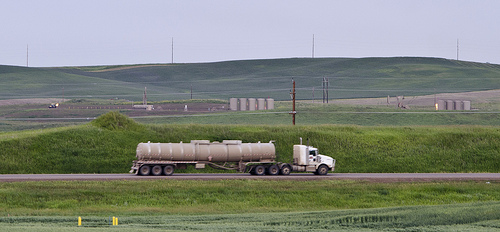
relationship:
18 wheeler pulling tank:
[129, 137, 337, 176] [132, 104, 289, 172]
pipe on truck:
[299, 132, 304, 145] [129, 132, 335, 175]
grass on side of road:
[2, 181, 497, 230] [2, 170, 497, 180]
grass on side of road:
[3, 118, 498, 174] [2, 170, 497, 180]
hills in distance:
[3, 55, 488, 97] [21, 60, 494, 137]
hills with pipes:
[0, 56, 500, 109] [190, 80, 280, 115]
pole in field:
[289, 75, 301, 124] [156, 78, 439, 122]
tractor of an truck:
[289, 133, 347, 193] [127, 126, 378, 182]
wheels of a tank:
[135, 161, 186, 178] [135, 139, 276, 161]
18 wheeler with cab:
[131, 137, 334, 176] [288, 135, 335, 173]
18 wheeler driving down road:
[129, 137, 337, 176] [34, 156, 498, 196]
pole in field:
[289, 78, 296, 126] [21, 113, 491, 172]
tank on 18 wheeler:
[132, 136, 278, 168] [129, 137, 337, 176]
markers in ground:
[75, 215, 119, 227] [0, 175, 497, 230]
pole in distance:
[457, 39, 458, 60] [3, 35, 494, 75]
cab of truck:
[288, 144, 338, 178] [129, 130, 360, 208]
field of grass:
[1, 171, 498, 226] [5, 189, 484, 209]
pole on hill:
[308, 30, 315, 57] [0, 54, 500, 110]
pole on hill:
[454, 37, 460, 60] [0, 54, 500, 110]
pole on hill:
[169, 35, 174, 63] [0, 54, 500, 110]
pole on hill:
[24, 42, 31, 67] [0, 54, 500, 110]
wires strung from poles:
[299, 74, 482, 97] [323, 73, 336, 106]